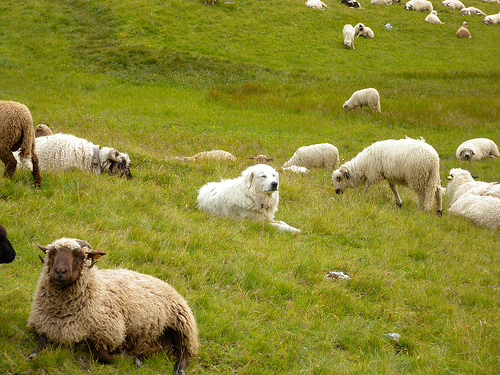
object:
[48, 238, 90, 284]
face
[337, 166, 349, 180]
ear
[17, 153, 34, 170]
tip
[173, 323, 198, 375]
leg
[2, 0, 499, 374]
field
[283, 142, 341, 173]
gray sheep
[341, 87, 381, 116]
gray sheep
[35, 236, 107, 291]
head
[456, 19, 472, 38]
animal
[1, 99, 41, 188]
sheep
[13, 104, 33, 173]
tail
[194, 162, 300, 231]
animal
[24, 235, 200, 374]
animal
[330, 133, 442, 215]
animal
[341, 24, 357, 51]
animal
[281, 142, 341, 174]
animal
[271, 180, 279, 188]
nose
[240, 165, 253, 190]
right ear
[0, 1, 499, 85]
hill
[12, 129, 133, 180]
sheep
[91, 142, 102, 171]
collar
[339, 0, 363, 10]
sheep